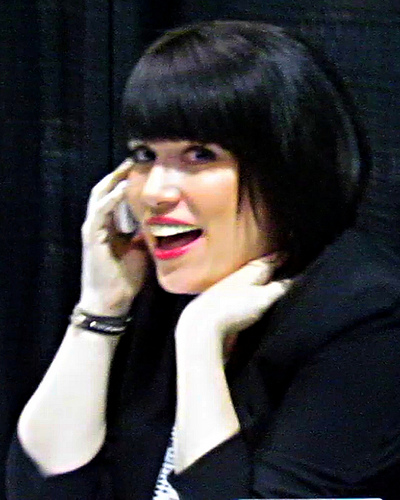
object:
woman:
[5, 20, 399, 498]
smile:
[143, 215, 209, 259]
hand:
[80, 153, 156, 310]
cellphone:
[112, 196, 141, 235]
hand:
[175, 245, 304, 350]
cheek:
[126, 168, 150, 216]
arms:
[5, 301, 129, 500]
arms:
[173, 317, 400, 500]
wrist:
[58, 288, 132, 353]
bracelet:
[68, 303, 137, 337]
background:
[0, 0, 399, 500]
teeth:
[150, 221, 198, 238]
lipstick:
[143, 215, 198, 226]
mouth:
[143, 215, 209, 262]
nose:
[139, 158, 181, 211]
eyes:
[128, 141, 158, 167]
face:
[125, 139, 237, 294]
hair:
[119, 16, 375, 284]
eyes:
[178, 140, 225, 171]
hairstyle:
[116, 18, 375, 283]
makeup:
[123, 137, 274, 296]